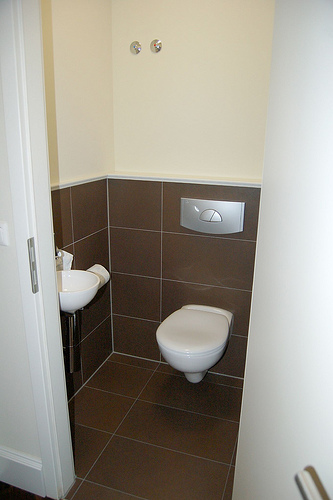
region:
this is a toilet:
[145, 295, 242, 403]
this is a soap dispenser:
[182, 195, 253, 250]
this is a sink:
[48, 252, 111, 322]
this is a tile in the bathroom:
[87, 429, 233, 498]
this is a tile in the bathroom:
[68, 381, 136, 440]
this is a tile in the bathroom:
[107, 223, 168, 281]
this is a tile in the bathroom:
[162, 232, 266, 299]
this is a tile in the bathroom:
[110, 310, 161, 371]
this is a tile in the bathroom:
[66, 176, 111, 236]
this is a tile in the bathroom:
[78, 318, 127, 380]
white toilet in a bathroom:
[154, 304, 234, 382]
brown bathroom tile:
[84, 384, 221, 448]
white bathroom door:
[271, 76, 324, 463]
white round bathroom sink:
[54, 268, 96, 308]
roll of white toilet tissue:
[88, 264, 111, 291]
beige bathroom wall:
[118, 58, 255, 173]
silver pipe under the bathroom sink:
[65, 313, 76, 375]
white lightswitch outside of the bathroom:
[0, 223, 8, 246]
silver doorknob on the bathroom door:
[292, 469, 327, 499]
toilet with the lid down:
[154, 303, 232, 379]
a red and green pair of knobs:
[128, 39, 160, 54]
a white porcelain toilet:
[154, 304, 237, 383]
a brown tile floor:
[120, 395, 240, 463]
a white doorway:
[1, 84, 83, 494]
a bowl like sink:
[47, 249, 97, 306]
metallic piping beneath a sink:
[60, 312, 81, 370]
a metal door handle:
[288, 473, 313, 498]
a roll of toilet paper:
[87, 264, 110, 285]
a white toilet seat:
[158, 304, 234, 385]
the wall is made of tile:
[128, 227, 179, 276]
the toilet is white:
[155, 295, 231, 383]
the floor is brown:
[103, 400, 162, 461]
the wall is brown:
[135, 232, 174, 282]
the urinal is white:
[59, 230, 113, 326]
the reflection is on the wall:
[165, 254, 241, 299]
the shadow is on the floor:
[162, 397, 216, 432]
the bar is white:
[290, 462, 318, 494]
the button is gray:
[170, 193, 247, 242]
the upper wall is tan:
[199, 49, 260, 108]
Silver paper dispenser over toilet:
[172, 184, 245, 241]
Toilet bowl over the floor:
[153, 287, 232, 377]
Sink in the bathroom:
[58, 236, 110, 322]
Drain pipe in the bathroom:
[65, 313, 90, 387]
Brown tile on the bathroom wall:
[106, 180, 175, 260]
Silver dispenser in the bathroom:
[175, 197, 253, 242]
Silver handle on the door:
[23, 226, 58, 293]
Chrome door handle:
[297, 456, 313, 485]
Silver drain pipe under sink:
[67, 317, 85, 378]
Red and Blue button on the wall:
[128, 33, 164, 56]